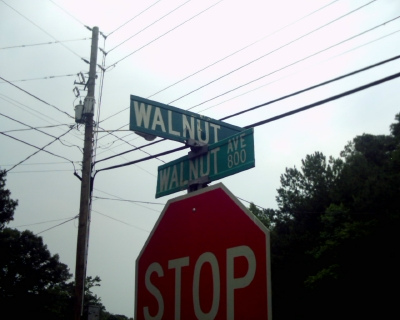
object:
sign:
[134, 183, 274, 320]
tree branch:
[267, 197, 326, 285]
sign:
[131, 93, 255, 200]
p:
[225, 244, 257, 318]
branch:
[329, 157, 344, 167]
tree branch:
[280, 168, 306, 194]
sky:
[3, 0, 399, 316]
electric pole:
[67, 27, 102, 319]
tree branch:
[12, 228, 52, 281]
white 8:
[228, 155, 233, 169]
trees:
[276, 112, 400, 319]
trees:
[1, 168, 123, 320]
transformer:
[74, 96, 94, 122]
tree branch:
[300, 148, 336, 197]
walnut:
[133, 103, 223, 144]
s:
[141, 264, 167, 319]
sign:
[129, 92, 241, 149]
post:
[73, 28, 104, 319]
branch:
[40, 254, 70, 288]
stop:
[143, 243, 256, 319]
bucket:
[73, 104, 85, 123]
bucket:
[83, 95, 96, 116]